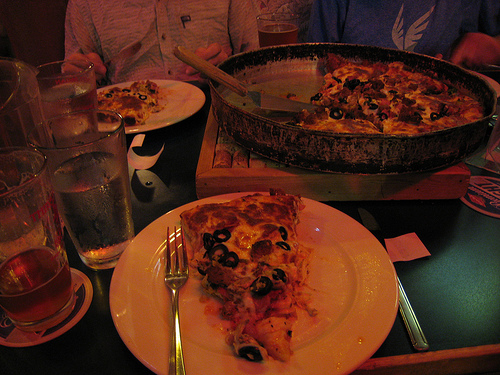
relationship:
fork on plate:
[163, 226, 190, 373] [108, 189, 402, 373]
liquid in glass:
[65, 170, 143, 257] [0, 157, 63, 329]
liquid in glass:
[51, 151, 135, 263] [26, 106, 136, 270]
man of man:
[61, 1, 262, 82] [59, 1, 260, 82]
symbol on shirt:
[376, 3, 444, 62] [292, 5, 469, 54]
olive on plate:
[251, 272, 274, 294] [108, 189, 402, 373]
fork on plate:
[164, 226, 190, 375] [324, 235, 407, 327]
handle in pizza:
[173, 45, 329, 114] [201, 44, 496, 167]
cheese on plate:
[178, 187, 318, 362] [108, 189, 402, 373]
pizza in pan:
[285, 55, 485, 134] [196, 50, 483, 161]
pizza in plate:
[96, 87, 148, 115] [108, 189, 402, 373]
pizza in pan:
[207, 34, 499, 171] [196, 50, 483, 161]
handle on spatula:
[169, 42, 251, 101] [177, 37, 324, 137]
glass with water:
[24, 107, 151, 272] [52, 154, 139, 271]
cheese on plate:
[178, 187, 318, 362] [123, 176, 398, 343]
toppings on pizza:
[223, 232, 284, 293] [180, 190, 324, 352]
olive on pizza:
[213, 227, 232, 243] [167, 187, 309, 367]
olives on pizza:
[277, 222, 294, 243] [167, 187, 309, 367]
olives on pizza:
[273, 239, 295, 254] [167, 187, 309, 367]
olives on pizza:
[266, 264, 288, 282] [167, 187, 309, 367]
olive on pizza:
[249, 275, 273, 299] [167, 187, 309, 367]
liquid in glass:
[51, 151, 135, 263] [34, 105, 148, 255]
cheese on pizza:
[180, 185, 317, 362] [179, 186, 316, 363]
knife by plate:
[350, 207, 429, 353] [116, 195, 364, 372]